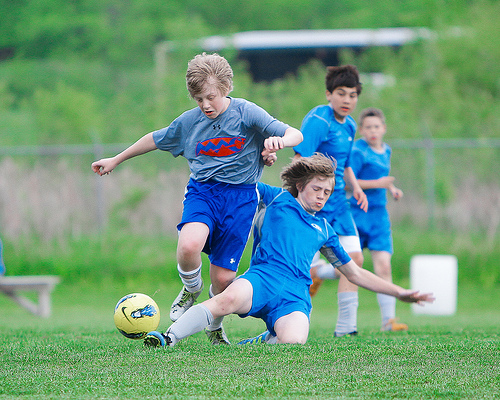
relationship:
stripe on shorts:
[249, 187, 261, 207] [172, 174, 259, 278]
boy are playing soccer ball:
[88, 51, 303, 348] [110, 292, 162, 341]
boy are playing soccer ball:
[142, 147, 437, 350] [110, 292, 162, 341]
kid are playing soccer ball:
[291, 62, 371, 337] [110, 292, 162, 341]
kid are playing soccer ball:
[303, 107, 409, 333] [110, 292, 162, 341]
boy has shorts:
[143, 152, 438, 347] [230, 260, 315, 327]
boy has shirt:
[88, 51, 303, 348] [150, 112, 287, 202]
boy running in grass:
[88, 51, 303, 348] [2, 290, 497, 396]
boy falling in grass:
[142, 147, 437, 350] [9, 341, 497, 399]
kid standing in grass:
[309, 107, 409, 330] [0, 322, 499, 398]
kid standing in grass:
[291, 62, 368, 338] [0, 322, 499, 398]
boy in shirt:
[88, 47, 309, 329] [251, 187, 351, 286]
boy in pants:
[88, 51, 303, 348] [171, 166, 282, 277]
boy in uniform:
[142, 147, 437, 350] [234, 175, 349, 335]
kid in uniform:
[291, 62, 371, 337] [159, 105, 261, 183]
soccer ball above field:
[110, 292, 186, 352] [26, 59, 492, 379]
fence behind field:
[2, 136, 499, 262] [0, 238, 497, 398]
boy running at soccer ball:
[88, 51, 303, 348] [103, 272, 164, 347]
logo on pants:
[228, 253, 240, 265] [173, 175, 263, 274]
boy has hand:
[88, 47, 309, 329] [263, 135, 284, 153]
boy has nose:
[88, 51, 303, 348] [201, 97, 210, 109]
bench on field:
[1, 275, 60, 316] [22, 349, 495, 393]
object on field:
[410, 253, 457, 315] [23, 290, 498, 397]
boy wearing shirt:
[88, 51, 303, 348] [154, 95, 288, 185]